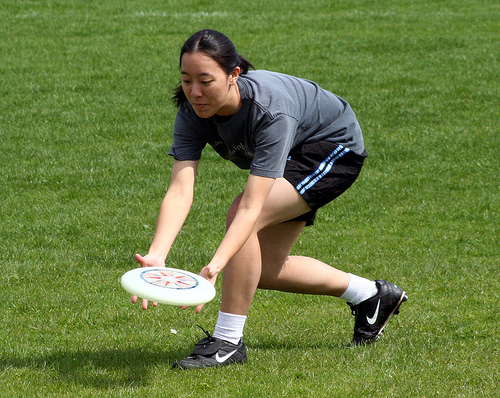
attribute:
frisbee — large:
[118, 264, 221, 308]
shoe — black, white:
[167, 334, 249, 370]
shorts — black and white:
[275, 134, 365, 224]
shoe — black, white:
[172, 331, 249, 369]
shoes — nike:
[168, 282, 418, 365]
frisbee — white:
[91, 256, 213, 316]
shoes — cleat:
[182, 328, 260, 375]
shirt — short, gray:
[166, 70, 363, 178]